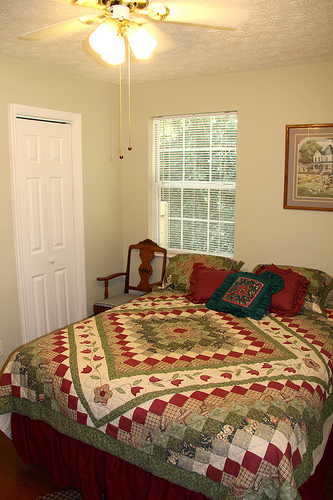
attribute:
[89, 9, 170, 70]
lights — turned on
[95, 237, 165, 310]
chair — wooden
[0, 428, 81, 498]
floor — brown, wooden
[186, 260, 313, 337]
pillows — red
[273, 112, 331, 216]
painting — framed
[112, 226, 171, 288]
chair — wooden, brown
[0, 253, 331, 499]
bedspread — decorative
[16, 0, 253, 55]
fan — white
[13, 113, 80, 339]
door — white, wooden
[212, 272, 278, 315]
cover — green